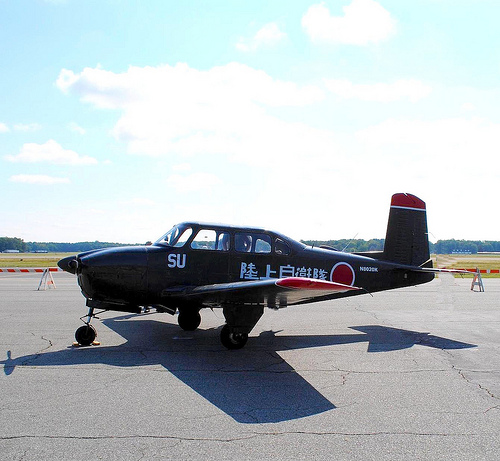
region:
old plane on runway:
[27, 196, 449, 334]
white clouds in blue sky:
[8, 0, 70, 70]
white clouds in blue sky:
[74, 75, 166, 142]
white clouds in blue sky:
[12, 108, 70, 176]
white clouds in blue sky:
[182, 25, 236, 82]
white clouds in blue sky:
[211, 141, 261, 171]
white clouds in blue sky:
[294, 31, 356, 99]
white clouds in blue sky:
[277, 138, 334, 193]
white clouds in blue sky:
[384, 59, 416, 93]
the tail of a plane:
[384, 193, 432, 266]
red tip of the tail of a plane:
[389, 191, 426, 211]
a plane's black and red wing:
[170, 277, 359, 303]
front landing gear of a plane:
[74, 306, 99, 343]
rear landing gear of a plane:
[222, 307, 259, 347]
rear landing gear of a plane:
[178, 312, 202, 327]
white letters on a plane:
[165, 252, 185, 267]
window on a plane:
[193, 227, 230, 253]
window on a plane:
[233, 231, 268, 252]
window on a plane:
[154, 224, 190, 246]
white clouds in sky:
[3, 2, 497, 238]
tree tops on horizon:
[0, 236, 498, 252]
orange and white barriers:
[0, 266, 55, 284]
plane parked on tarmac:
[60, 190, 477, 347]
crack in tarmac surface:
[0, 423, 474, 453]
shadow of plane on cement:
[7, 316, 474, 424]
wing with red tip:
[193, 272, 360, 310]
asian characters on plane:
[235, 261, 331, 281]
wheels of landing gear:
[72, 312, 252, 344]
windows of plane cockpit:
[163, 224, 270, 249]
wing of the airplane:
[279, 272, 354, 311]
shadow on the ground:
[216, 366, 299, 424]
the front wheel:
[75, 322, 104, 344]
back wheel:
[224, 326, 247, 344]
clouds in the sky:
[114, 107, 258, 171]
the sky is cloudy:
[131, 117, 191, 151]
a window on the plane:
[200, 232, 230, 252]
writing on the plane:
[236, 262, 269, 276]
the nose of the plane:
[58, 257, 82, 273]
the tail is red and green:
[388, 192, 425, 262]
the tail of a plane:
[385, 189, 434, 286]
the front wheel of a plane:
[74, 324, 96, 345]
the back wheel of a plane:
[220, 322, 246, 345]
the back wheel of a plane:
[174, 311, 201, 331]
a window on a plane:
[191, 227, 228, 250]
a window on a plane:
[233, 228, 270, 255]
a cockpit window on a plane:
[157, 220, 192, 247]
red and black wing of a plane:
[195, 275, 355, 305]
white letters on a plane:
[166, 246, 188, 270]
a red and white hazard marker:
[0, 264, 60, 288]